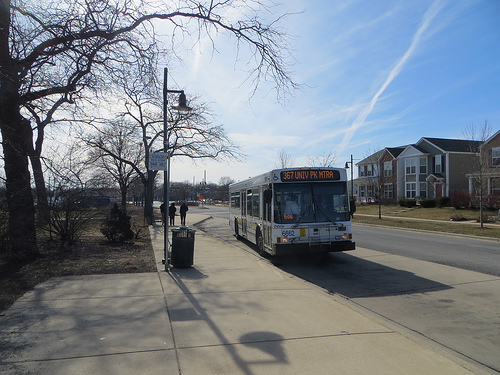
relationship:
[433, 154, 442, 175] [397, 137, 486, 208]
window on house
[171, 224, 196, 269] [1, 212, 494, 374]
trash can on sidewalk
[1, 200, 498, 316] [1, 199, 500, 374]
grass on ground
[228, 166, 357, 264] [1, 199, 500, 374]
bus on ground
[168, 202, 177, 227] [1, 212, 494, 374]
person on sidewalk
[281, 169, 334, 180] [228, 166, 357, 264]
text on bus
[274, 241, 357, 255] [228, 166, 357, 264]
bumper on bus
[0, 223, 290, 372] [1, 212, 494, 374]
shadow on sidewalk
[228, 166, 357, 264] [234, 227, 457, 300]
bus has a shadow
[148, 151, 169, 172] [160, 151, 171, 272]
sign on pole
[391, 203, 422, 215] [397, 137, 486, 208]
steps to house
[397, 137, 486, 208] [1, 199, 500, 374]
house near ground